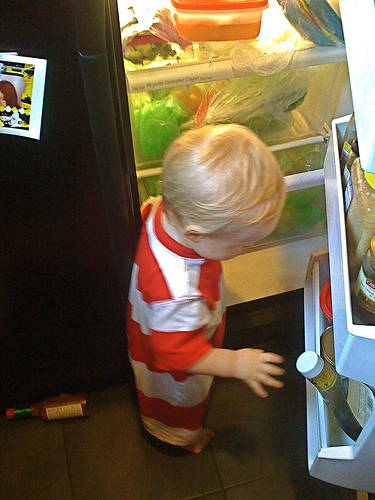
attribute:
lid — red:
[171, 0, 271, 11]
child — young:
[125, 122, 285, 455]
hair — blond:
[155, 124, 274, 215]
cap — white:
[288, 348, 319, 383]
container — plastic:
[170, 2, 273, 44]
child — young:
[116, 139, 283, 443]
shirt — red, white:
[113, 193, 233, 446]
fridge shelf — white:
[320, 110, 372, 385]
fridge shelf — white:
[301, 245, 372, 492]